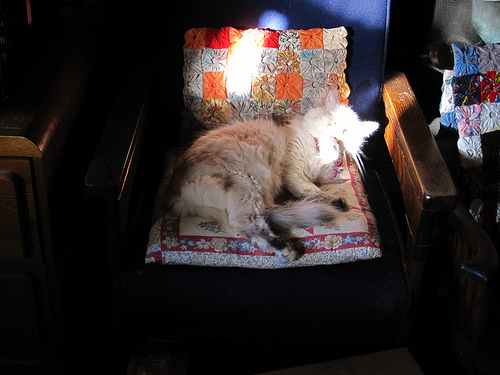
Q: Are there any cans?
A: No, there are no cans.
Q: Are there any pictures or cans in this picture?
A: No, there are no cans or pictures.